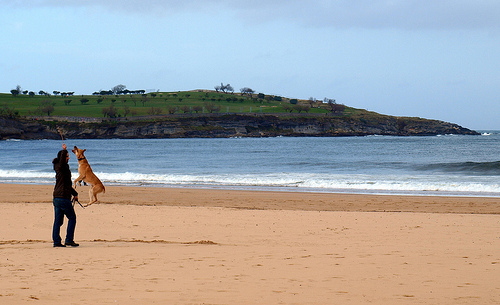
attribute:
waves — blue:
[1, 167, 499, 199]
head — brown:
[72, 141, 86, 155]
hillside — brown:
[1, 91, 481, 140]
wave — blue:
[132, 167, 492, 204]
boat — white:
[478, 130, 491, 137]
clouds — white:
[190, 2, 499, 21]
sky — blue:
[0, 2, 495, 124]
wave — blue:
[406, 153, 498, 173]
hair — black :
[58, 150, 65, 160]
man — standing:
[51, 145, 79, 250]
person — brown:
[46, 138, 81, 249]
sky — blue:
[295, 28, 455, 93]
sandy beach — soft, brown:
[158, 138, 322, 276]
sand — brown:
[143, 244, 405, 289]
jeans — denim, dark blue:
[46, 206, 88, 260]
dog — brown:
[67, 144, 116, 204]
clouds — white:
[103, 21, 228, 43]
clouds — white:
[269, 29, 409, 74]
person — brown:
[54, 144, 81, 249]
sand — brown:
[118, 194, 491, 303]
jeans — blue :
[46, 193, 82, 250]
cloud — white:
[5, 2, 499, 32]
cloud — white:
[5, 15, 497, 132]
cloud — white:
[442, 77, 467, 88]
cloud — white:
[252, 45, 286, 64]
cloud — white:
[322, 48, 364, 80]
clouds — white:
[15, 18, 100, 63]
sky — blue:
[394, 31, 483, 91]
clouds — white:
[284, 45, 374, 95]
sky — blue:
[72, 25, 140, 66]